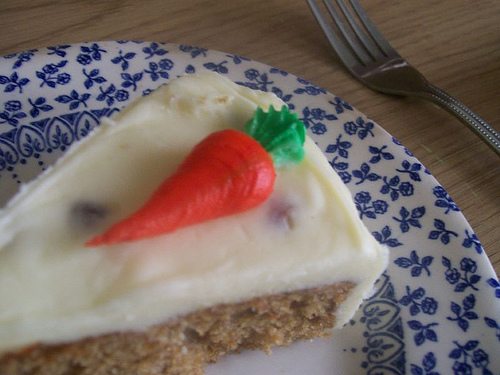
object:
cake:
[0, 71, 389, 369]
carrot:
[82, 103, 307, 250]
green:
[243, 104, 307, 163]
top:
[0, 76, 383, 353]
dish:
[1, 39, 499, 374]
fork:
[308, 0, 499, 159]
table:
[0, 0, 500, 275]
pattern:
[12, 50, 173, 84]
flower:
[34, 60, 76, 91]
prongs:
[307, 0, 414, 73]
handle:
[430, 90, 499, 159]